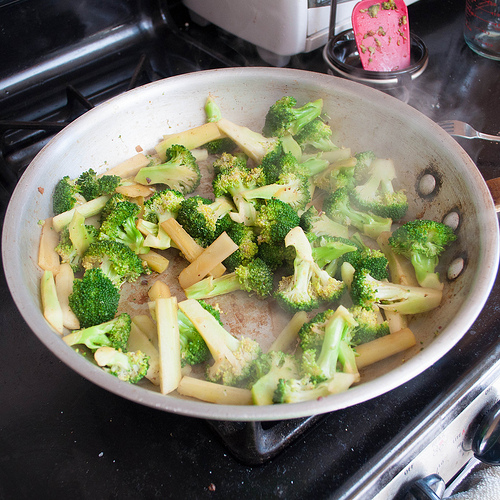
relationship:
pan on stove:
[9, 65, 499, 423] [1, 5, 500, 497]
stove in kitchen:
[1, 5, 500, 497] [2, 3, 499, 499]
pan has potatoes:
[9, 65, 499, 423] [160, 209, 236, 284]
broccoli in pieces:
[139, 147, 198, 193] [273, 98, 320, 142]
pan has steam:
[9, 65, 499, 423] [307, 39, 480, 232]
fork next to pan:
[443, 116, 500, 144] [9, 65, 499, 423]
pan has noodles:
[0, 65, 499, 423] [169, 118, 281, 161]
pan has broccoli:
[9, 65, 499, 423] [139, 147, 198, 193]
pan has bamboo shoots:
[9, 65, 499, 423] [162, 213, 235, 286]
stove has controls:
[1, 5, 500, 497] [469, 400, 499, 468]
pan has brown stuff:
[9, 65, 499, 423] [229, 299, 287, 345]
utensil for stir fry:
[448, 121, 499, 147] [52, 92, 455, 410]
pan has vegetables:
[9, 65, 499, 423] [50, 89, 452, 407]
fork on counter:
[443, 116, 500, 144] [3, 3, 499, 499]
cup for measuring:
[465, 3, 498, 61] [465, 7, 500, 28]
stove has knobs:
[1, 5, 500, 497] [472, 402, 500, 468]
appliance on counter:
[187, 2, 418, 71] [226, 7, 499, 203]